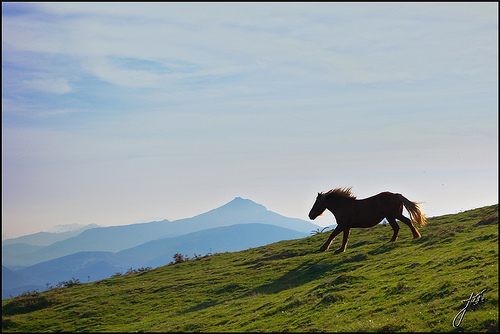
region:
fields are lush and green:
[7, 232, 469, 330]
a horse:
[290, 177, 427, 259]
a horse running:
[281, 172, 439, 253]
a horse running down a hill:
[223, 152, 496, 310]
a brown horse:
[280, 174, 462, 266]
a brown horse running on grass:
[231, 162, 487, 306]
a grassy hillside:
[71, 205, 497, 327]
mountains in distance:
[39, 186, 332, 284]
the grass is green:
[119, 215, 484, 332]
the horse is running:
[295, 171, 492, 278]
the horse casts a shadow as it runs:
[178, 160, 499, 311]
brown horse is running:
[294, 156, 444, 272]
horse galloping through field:
[289, 172, 440, 255]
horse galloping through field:
[249, 133, 462, 326]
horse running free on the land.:
[75, 105, 465, 288]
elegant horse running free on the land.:
[27, 66, 447, 261]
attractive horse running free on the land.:
[70, 91, 466, 271]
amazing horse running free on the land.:
[80, 76, 441, 271]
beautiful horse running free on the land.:
[91, 56, 443, 281]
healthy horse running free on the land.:
[74, 63, 470, 266]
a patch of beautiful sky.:
[40, 37, 430, 157]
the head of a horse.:
[291, 184, 351, 221]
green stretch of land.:
[68, 276, 430, 312]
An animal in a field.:
[303, 185, 435, 244]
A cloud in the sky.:
[86, 53, 170, 93]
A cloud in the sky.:
[18, 68, 75, 99]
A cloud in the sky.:
[19, 101, 493, 189]